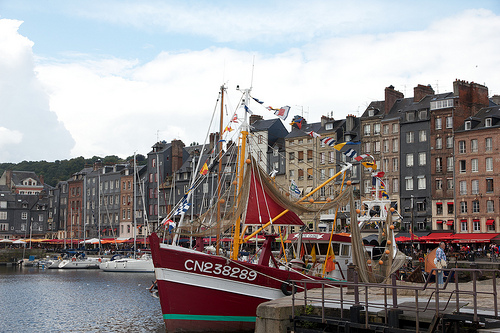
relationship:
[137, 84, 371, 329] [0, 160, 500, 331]
boat in harbor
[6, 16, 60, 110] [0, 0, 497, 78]
cloud in sky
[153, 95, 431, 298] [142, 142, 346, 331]
mast on ship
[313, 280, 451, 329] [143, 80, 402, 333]
dock by boat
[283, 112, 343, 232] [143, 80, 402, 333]
buildings behind boat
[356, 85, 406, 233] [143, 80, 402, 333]
buildings behind boat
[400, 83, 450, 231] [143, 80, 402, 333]
buildings behind boat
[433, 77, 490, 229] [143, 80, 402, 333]
buildings behind boat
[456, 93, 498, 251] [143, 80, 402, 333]
buildings behind boat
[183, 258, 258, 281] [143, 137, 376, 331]
identification number on ship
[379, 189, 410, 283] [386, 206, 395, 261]
rope with balls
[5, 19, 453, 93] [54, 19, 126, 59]
clouds in sky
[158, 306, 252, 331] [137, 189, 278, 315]
stripe on side of boat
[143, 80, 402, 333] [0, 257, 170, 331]
boat in water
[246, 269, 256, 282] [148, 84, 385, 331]
number on boat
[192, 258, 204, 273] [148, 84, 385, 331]
letter on boat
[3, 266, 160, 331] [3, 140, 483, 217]
water in front of buildings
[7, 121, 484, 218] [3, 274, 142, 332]
buildings in front of water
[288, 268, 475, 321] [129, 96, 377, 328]
pier on side of boat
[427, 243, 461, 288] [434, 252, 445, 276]
person in outfit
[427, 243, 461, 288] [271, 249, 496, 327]
person standing on pier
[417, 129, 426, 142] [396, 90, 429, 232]
window on front of building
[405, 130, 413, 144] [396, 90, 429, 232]
window on front of building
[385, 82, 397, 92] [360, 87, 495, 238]
chimney on top of building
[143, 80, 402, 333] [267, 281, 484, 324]
boat by dock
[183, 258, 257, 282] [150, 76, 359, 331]
identification number painted on boat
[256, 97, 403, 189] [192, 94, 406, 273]
pennants in rigging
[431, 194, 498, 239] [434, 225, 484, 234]
red awnings over window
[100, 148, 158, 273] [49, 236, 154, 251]
white boat at dock